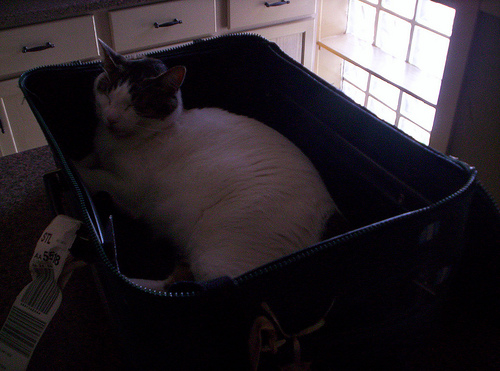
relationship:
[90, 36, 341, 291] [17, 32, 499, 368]
cat in black suitcase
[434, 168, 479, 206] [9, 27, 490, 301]
zipper around suitcase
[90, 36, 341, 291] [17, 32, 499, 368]
cat in a black suitcase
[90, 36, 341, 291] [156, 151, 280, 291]
cat has a white body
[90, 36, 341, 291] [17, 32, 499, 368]
cat in inside of black suitcase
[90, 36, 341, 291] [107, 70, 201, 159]
cat sleeping with a closed eyes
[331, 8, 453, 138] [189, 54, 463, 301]
window on ground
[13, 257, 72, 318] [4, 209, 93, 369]
bar code on paper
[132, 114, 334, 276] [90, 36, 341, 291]
fur on cat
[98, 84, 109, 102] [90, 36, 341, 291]
eye on cat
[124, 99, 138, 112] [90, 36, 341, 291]
eye on cat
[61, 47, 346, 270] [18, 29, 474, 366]
cat in box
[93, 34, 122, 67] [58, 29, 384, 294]
cat ear on cat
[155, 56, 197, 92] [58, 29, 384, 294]
cat ear on cat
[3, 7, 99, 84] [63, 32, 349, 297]
drawer behind cat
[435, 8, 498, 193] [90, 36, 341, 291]
wall beside cat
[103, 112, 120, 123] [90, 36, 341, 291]
nose on cat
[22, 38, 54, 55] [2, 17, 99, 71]
handle on drawer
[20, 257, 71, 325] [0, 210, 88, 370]
bar code on paper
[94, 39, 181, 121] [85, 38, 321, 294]
head of cat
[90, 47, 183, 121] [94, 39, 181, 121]
patch on head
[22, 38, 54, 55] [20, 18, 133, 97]
handle on drawer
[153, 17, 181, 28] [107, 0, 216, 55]
handle on drawer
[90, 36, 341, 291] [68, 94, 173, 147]
cat with whiskers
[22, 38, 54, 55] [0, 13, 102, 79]
handle on drawer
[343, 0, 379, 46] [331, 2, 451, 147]
panels on window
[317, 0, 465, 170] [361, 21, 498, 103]
panels are on window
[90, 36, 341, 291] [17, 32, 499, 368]
cat laying in a black suitcase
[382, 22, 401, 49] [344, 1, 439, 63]
light coming out of window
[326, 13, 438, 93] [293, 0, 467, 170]
pane on window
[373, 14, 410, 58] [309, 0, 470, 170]
pane on window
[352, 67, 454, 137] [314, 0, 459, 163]
pane on window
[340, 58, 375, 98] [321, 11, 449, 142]
pane on window